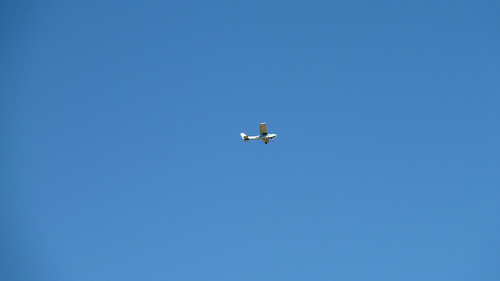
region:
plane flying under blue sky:
[46, 10, 467, 267]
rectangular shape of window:
[256, 120, 271, 140]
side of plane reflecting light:
[235, 120, 275, 145]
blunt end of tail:
[235, 121, 250, 141]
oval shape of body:
[240, 126, 275, 141]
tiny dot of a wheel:
[265, 130, 275, 142]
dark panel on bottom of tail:
[240, 130, 250, 140]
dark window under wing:
[260, 126, 270, 133]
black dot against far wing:
[260, 135, 270, 141]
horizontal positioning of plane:
[238, 113, 279, 149]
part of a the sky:
[181, 202, 227, 269]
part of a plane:
[245, 110, 287, 174]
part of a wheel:
[262, 138, 276, 152]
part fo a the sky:
[202, 221, 241, 278]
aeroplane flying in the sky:
[231, 115, 292, 153]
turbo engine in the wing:
[258, 119, 270, 134]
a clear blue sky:
[333, 34, 442, 242]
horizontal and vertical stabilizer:
[239, 130, 246, 143]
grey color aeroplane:
[236, 115, 293, 147]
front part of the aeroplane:
[272, 131, 276, 141]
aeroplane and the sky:
[218, 85, 334, 180]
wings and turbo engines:
[258, 119, 270, 146]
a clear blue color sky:
[36, 32, 214, 249]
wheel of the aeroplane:
[262, 138, 270, 145]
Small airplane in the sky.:
[236, 120, 278, 145]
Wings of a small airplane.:
[257, 117, 269, 143]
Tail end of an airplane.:
[238, 128, 248, 141]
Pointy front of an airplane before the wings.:
[268, 131, 277, 141]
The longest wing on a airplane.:
[256, 118, 268, 136]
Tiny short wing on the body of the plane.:
[260, 136, 268, 143]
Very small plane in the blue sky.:
[236, 120, 278, 145]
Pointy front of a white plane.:
[264, 128, 278, 141]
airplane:
[235, 121, 309, 159]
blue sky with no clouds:
[19, 6, 110, 81]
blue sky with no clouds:
[22, 75, 132, 156]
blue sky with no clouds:
[36, 138, 128, 206]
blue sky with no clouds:
[37, 169, 131, 241]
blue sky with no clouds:
[153, 196, 228, 253]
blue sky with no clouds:
[216, 169, 303, 260]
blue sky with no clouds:
[310, 178, 395, 278]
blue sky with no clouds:
[342, 69, 393, 161]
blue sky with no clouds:
[166, 42, 233, 103]